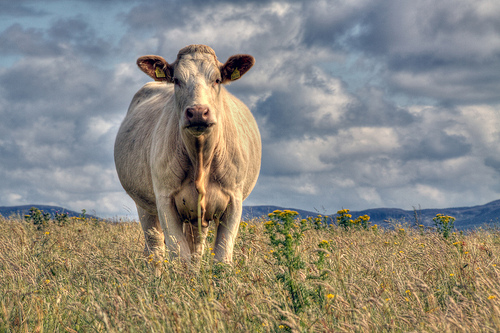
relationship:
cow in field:
[112, 44, 263, 267] [3, 205, 500, 331]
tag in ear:
[154, 66, 165, 78] [136, 54, 173, 84]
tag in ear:
[230, 68, 240, 80] [222, 55, 257, 82]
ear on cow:
[136, 54, 173, 84] [112, 44, 263, 267]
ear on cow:
[222, 55, 257, 82] [112, 44, 263, 267]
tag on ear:
[154, 66, 165, 78] [136, 54, 173, 84]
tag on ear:
[230, 68, 240, 80] [222, 55, 257, 82]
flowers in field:
[20, 205, 499, 332] [3, 205, 500, 331]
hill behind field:
[0, 199, 499, 226] [3, 205, 500, 331]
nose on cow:
[185, 106, 209, 124] [112, 44, 263, 267]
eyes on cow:
[172, 77, 221, 87] [112, 44, 263, 267]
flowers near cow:
[20, 205, 499, 332] [112, 44, 263, 267]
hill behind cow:
[0, 199, 499, 226] [112, 44, 263, 267]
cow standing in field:
[112, 44, 263, 267] [3, 205, 500, 331]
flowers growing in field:
[20, 205, 499, 332] [3, 205, 500, 331]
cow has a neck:
[112, 44, 263, 267] [181, 121, 216, 170]